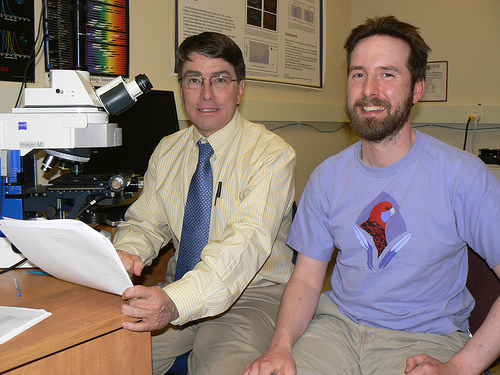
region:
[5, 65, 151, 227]
a scientific microscope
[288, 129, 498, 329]
a light blue t-shirt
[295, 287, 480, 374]
a pair of light tan pants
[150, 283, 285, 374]
a pair of light tan pants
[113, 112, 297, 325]
a yellow dress shirt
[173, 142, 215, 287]
a shiny blue men's tie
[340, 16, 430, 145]
a man's bearded face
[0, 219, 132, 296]
a stack of papers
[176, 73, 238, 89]
a pair of eyeglasses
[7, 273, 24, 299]
a blue ink pen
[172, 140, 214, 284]
Blue tie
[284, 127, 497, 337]
A purple shirt with a red bird on it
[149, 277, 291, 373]
Khaki pants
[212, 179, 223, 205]
The top of a pen in a shirt pocket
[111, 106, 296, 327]
A yellow long sleeve button up shirt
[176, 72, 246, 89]
Metal framed glasses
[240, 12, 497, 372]
A middle aged man with a short beard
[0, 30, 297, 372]
An older well dressed man holding paper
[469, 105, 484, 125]
An electrical outlet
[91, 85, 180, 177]
A computer monitor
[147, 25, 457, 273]
Two men that might be scientists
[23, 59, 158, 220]
A telescope that is white and black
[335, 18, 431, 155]
Man with dark hair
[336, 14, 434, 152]
Man has a beard and mustache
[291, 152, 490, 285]
A red bird on a blue shirt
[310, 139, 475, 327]
A light blue t-shirt with a bird on it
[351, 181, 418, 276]
A red and black bird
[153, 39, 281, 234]
A man with glasses in a yellow shirt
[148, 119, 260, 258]
A yellow shirt and a blue tie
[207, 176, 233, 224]
A black pen in a shirt pocket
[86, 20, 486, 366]
two men sitting down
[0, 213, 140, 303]
the papers in the man's hand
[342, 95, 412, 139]
the man's facial hair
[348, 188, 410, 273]
the design on the front of the man's shirt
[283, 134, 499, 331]
the man's light purple shirt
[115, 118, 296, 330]
the man's long sleeved shirt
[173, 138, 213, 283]
the man's long blue tie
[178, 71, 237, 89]
the glasses on the man's face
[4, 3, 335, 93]
the posters hanging on the wall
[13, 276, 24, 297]
the pen on the desk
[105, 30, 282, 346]
guy wearing glasses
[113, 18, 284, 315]
guy wearing yellow shirt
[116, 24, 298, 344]
guy wearing a blue tie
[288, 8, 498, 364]
guy wearing a blue shirt with a red bird on it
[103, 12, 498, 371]
two guys smiling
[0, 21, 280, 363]
guy holding papers in his hand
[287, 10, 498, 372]
guy with beard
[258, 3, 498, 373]
guy with mustache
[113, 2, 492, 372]
two guys with short brown hair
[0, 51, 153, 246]
white and black microscope